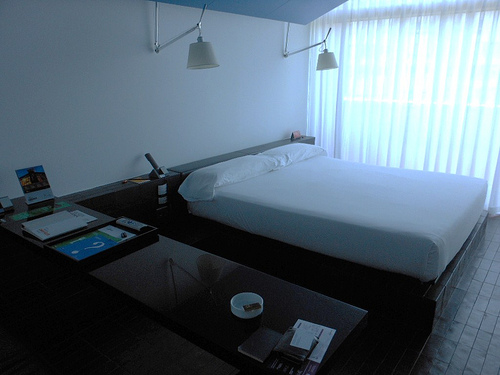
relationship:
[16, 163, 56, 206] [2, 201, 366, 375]
calender on table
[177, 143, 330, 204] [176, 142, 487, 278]
pillows on bedspread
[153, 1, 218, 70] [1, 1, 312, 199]
lamp hanging on wall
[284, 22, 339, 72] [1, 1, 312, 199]
lamp hanging on wall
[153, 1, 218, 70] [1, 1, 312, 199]
lamp on wall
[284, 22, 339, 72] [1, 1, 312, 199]
lamp on wall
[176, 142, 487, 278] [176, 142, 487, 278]
bedspread has bedspread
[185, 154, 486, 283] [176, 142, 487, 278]
bed has bedspread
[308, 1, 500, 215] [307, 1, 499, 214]
curtains hang in window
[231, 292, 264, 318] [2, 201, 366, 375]
ashtray on table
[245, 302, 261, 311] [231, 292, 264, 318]
matches in ashtray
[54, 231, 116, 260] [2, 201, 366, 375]
brochure on table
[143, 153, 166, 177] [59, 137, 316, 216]
phone on headboard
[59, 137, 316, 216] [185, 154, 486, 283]
headboard beside bed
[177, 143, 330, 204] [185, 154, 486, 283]
pillows on bed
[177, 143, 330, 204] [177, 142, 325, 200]
pillows have pillow cases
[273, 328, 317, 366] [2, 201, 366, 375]
wallet on table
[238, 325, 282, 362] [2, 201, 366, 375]
book on table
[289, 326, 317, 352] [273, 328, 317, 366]
business card on wallet